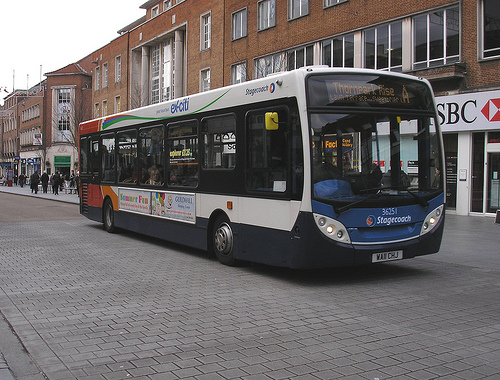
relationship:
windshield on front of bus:
[310, 109, 445, 209] [219, 51, 450, 253]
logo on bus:
[366, 215, 410, 223] [78, 62, 447, 272]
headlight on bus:
[322, 222, 337, 237] [78, 62, 447, 272]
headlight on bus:
[425, 211, 437, 226] [78, 62, 447, 272]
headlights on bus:
[312, 209, 450, 246] [78, 62, 447, 272]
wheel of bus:
[208, 214, 242, 269] [78, 62, 447, 272]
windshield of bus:
[310, 109, 445, 203] [78, 62, 447, 272]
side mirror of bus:
[261, 106, 278, 131] [78, 62, 447, 272]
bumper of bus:
[299, 206, 445, 271] [78, 62, 447, 272]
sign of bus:
[322, 76, 430, 107] [78, 62, 447, 272]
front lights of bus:
[318, 216, 327, 227] [78, 62, 447, 272]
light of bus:
[420, 207, 442, 232] [78, 62, 447, 272]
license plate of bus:
[369, 249, 411, 265] [78, 62, 447, 272]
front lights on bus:
[318, 216, 345, 238] [78, 62, 447, 272]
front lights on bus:
[420, 205, 441, 235] [78, 62, 447, 272]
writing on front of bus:
[363, 208, 413, 229] [78, 62, 447, 272]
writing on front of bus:
[367, 208, 414, 240] [39, 67, 484, 277]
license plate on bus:
[369, 249, 403, 264] [97, 50, 461, 291]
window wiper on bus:
[335, 189, 396, 217] [78, 62, 447, 272]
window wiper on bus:
[397, 181, 432, 213] [78, 62, 447, 272]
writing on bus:
[164, 97, 191, 117] [78, 62, 447, 272]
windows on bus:
[3, 47, 470, 295] [78, 62, 447, 272]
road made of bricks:
[2, 190, 499, 378] [175, 351, 259, 377]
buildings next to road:
[1, 2, 499, 213] [2, 190, 499, 378]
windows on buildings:
[310, 3, 463, 79] [118, 0, 498, 215]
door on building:
[464, 130, 498, 215] [146, 1, 498, 219]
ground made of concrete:
[1, 179, 93, 208] [0, 188, 497, 378]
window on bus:
[314, 106, 447, 210] [78, 62, 447, 272]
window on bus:
[133, 121, 200, 191] [78, 62, 447, 272]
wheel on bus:
[213, 212, 242, 263] [53, 60, 453, 279]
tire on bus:
[97, 191, 123, 232] [53, 60, 453, 279]